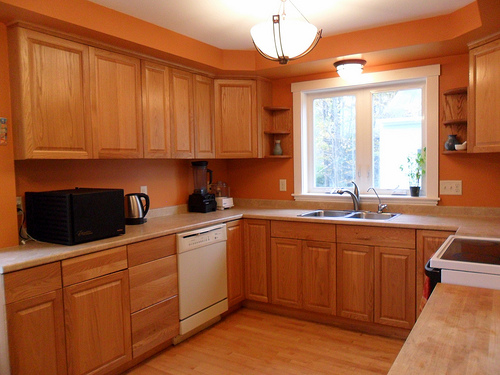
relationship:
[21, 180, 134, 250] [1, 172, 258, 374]
microwave on counter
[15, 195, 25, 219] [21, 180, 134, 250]
outlet by microwave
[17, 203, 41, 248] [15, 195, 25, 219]
plugs in outlet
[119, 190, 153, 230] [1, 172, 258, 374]
coffeepot on counter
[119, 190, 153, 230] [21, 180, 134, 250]
coffeepot beside microwave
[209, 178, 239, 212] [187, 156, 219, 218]
processor beside blender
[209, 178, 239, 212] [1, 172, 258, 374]
processor on counter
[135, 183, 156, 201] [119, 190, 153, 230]
outlet by coffeepot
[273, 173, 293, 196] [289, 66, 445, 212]
outlet beside window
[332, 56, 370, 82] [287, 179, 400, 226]
light above sink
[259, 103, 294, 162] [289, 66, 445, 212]
shelf beside window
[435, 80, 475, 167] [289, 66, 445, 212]
shelf beside window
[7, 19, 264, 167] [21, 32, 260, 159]
cabinets have doors